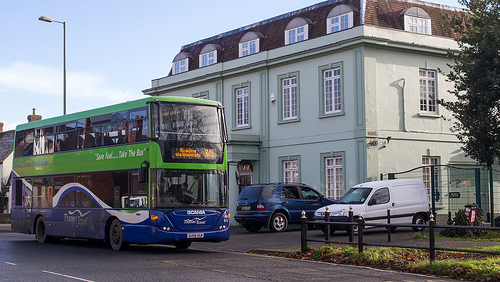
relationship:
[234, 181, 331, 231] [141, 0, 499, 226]
vehicle beside of building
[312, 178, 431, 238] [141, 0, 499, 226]
van beside of building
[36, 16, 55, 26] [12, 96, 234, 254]
street light above bus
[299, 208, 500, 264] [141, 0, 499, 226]
fence in front of building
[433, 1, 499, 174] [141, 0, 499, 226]
tree beside of building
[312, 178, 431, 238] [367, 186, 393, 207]
van has a window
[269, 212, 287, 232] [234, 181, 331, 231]
tire on vehicle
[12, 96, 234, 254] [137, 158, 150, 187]
bus has a mirror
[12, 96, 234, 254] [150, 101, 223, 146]
bus has a window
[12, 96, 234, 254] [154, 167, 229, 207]
bus has a window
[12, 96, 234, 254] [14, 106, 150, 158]
bus has a window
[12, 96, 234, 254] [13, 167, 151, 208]
bus has a window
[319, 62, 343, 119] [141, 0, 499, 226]
window on building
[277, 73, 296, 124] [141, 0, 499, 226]
window on building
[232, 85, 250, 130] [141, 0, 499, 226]
window on building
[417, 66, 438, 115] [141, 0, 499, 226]
window on building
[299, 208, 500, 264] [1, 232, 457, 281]
fence beside street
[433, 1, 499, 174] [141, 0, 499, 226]
tree beside building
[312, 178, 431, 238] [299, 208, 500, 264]
van beside fence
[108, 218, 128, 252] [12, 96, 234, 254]
tire on bus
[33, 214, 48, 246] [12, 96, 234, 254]
tire on bus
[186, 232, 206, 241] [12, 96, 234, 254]
tag on bus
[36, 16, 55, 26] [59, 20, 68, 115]
street light on a post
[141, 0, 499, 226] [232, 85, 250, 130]
building has a window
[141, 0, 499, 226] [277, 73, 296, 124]
building has a window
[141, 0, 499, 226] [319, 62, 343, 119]
building has a window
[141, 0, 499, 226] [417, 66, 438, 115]
building has a window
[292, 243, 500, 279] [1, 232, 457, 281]
grass beside street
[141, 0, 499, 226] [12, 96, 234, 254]
building beside bus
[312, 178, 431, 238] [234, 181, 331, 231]
van parked beside vehicle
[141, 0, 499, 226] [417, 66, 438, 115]
building has window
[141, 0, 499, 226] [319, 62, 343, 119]
building has window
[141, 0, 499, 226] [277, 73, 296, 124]
building has window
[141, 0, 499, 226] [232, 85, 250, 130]
building has window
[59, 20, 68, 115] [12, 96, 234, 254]
post behind bus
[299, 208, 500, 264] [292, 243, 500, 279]
fence beside grass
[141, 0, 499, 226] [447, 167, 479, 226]
building has a door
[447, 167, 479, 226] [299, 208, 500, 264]
door close to fence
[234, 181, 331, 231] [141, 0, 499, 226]
vehicle beside building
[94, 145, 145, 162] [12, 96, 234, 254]
letters are on bus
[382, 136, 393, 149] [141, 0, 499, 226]
camera on building